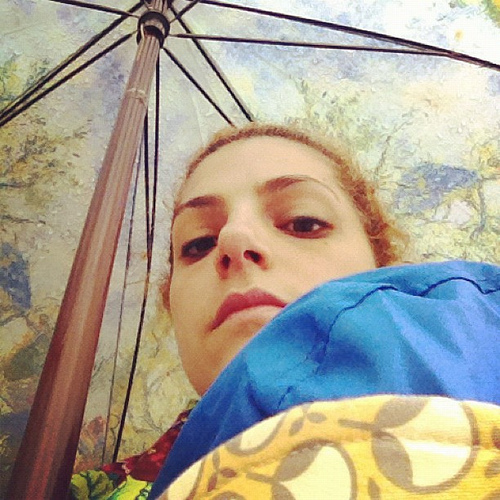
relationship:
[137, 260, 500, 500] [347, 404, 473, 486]
cloth has leaf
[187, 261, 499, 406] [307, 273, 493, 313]
cloth has lines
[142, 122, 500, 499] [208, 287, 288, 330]
woman has lip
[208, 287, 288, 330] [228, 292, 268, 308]
lip have lipstick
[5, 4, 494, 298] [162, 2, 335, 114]
umbrella has frame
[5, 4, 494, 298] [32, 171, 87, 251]
umbrella has drops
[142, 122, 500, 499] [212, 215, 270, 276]
woman has nose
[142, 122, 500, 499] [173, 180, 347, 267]
woman has eyes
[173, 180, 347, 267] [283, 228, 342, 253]
eyes have lines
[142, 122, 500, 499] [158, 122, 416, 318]
woman has hair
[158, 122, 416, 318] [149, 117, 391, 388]
hair on head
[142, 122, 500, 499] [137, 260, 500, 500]
woman has cloth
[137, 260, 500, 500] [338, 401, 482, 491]
cloth has pattern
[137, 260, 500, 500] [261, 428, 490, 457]
cloth has stitching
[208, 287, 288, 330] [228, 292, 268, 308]
lip with no lipstick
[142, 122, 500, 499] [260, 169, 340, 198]
woman has eyebrow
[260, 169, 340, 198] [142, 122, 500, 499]
eyebrow on woman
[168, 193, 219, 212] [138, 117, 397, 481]
eyebrow of woman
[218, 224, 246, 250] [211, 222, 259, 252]
tip of nose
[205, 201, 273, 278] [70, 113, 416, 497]
nose belonging to woman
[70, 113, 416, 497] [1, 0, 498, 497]
woman holding umbrella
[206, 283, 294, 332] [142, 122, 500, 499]
lip belonging to woman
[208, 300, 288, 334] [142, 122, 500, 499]
lip belonging to woman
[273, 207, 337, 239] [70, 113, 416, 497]
eyeball belonging to woman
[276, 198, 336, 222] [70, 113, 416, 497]
eyelid belonging to woman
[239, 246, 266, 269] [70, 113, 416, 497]
nostril belonging to woman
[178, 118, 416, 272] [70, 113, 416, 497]
hair belonging to woman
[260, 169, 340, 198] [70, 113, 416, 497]
eyebrow belonging to woman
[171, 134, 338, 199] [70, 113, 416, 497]
forehead belonging to woman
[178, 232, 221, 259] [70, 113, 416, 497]
eyes belonging to woman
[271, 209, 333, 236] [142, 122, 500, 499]
eye belonging to woman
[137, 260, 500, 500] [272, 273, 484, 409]
cloth held together by seam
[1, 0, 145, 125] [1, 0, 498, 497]
stem supporting umbrella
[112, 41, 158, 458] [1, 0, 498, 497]
stem supporting umbrella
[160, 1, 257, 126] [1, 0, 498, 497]
stem supporting umbrella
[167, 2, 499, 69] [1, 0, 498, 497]
stem supporting umbrella